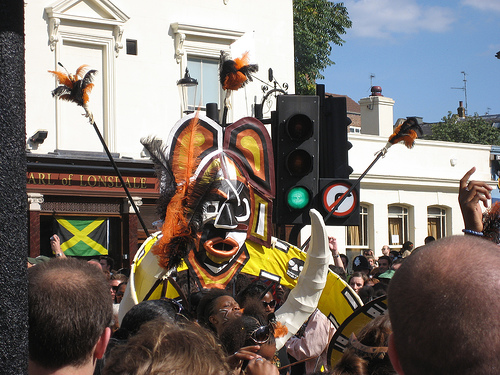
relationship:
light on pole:
[286, 187, 308, 209] [274, 213, 304, 248]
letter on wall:
[30, 165, 157, 190] [27, 157, 164, 277]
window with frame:
[200, 58, 219, 109] [166, 20, 243, 150]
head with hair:
[381, 220, 493, 372] [410, 290, 470, 342]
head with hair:
[22, 256, 119, 371] [22, 284, 90, 352]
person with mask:
[117, 112, 364, 339] [164, 105, 275, 275]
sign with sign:
[318, 178, 360, 224] [320, 181, 355, 216]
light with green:
[286, 187, 308, 209] [284, 187, 308, 210]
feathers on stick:
[47, 62, 100, 117] [82, 104, 154, 254]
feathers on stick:
[215, 47, 254, 95] [220, 95, 237, 135]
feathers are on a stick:
[388, 110, 420, 150] [328, 118, 423, 218]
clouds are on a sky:
[329, 3, 489, 49] [310, 0, 492, 130]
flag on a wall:
[45, 213, 110, 258] [17, 191, 156, 274]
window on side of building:
[186, 54, 226, 125] [18, 0, 497, 370]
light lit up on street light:
[286, 187, 308, 209] [274, 93, 319, 227]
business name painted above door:
[24, 170, 148, 190] [38, 210, 123, 270]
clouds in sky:
[329, 0, 499, 39] [304, 18, 481, 122]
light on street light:
[286, 187, 308, 209] [274, 93, 319, 225]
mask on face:
[193, 150, 252, 261] [194, 173, 254, 262]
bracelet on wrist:
[460, 228, 483, 234] [460, 219, 482, 233]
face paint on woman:
[214, 305, 231, 321] [187, 289, 254, 336]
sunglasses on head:
[256, 329, 278, 347] [216, 306, 289, 368]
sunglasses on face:
[262, 297, 275, 306] [259, 290, 276, 320]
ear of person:
[97, 326, 117, 362] [27, 256, 112, 374]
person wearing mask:
[137, 117, 377, 336] [192, 150, 252, 273]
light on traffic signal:
[289, 187, 319, 214] [275, 86, 315, 230]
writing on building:
[24, 170, 164, 190] [32, 4, 333, 252]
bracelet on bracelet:
[460, 228, 483, 234] [460, 228, 483, 234]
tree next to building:
[294, 1, 344, 89] [29, 1, 309, 265]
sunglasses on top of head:
[250, 320, 275, 342] [223, 314, 286, 363]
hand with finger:
[454, 161, 484, 233] [458, 163, 472, 192]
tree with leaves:
[291, 0, 352, 95] [303, 6, 326, 49]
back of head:
[20, 247, 118, 362] [28, 255, 114, 370]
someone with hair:
[104, 313, 222, 370] [96, 321, 240, 371]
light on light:
[286, 187, 308, 209] [286, 187, 308, 209]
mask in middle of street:
[164, 105, 275, 275] [20, 226, 498, 373]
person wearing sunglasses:
[247, 285, 280, 315] [262, 300, 276, 306]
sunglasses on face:
[262, 300, 276, 306] [248, 289, 276, 319]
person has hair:
[27, 256, 112, 374] [30, 256, 106, 366]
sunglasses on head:
[250, 320, 275, 342] [222, 311, 280, 371]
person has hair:
[387, 225, 493, 373] [406, 277, 474, 341]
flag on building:
[50, 219, 108, 256] [24, 0, 297, 287]